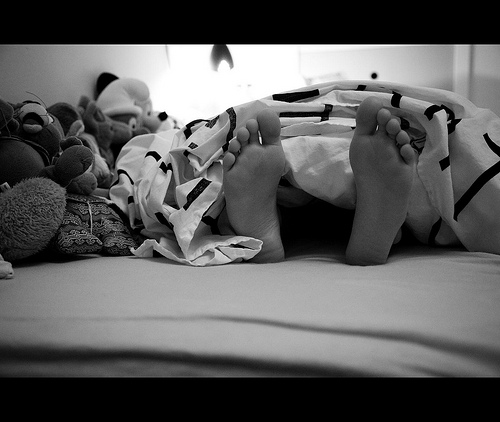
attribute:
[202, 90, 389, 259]
feet — bare, small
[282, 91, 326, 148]
blanket — white, here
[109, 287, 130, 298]
sheets — white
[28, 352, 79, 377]
bed — here, wrinkled, light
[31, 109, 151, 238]
animals — stuffed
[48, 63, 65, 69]
wall — light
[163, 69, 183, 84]
light — here, bright, shining